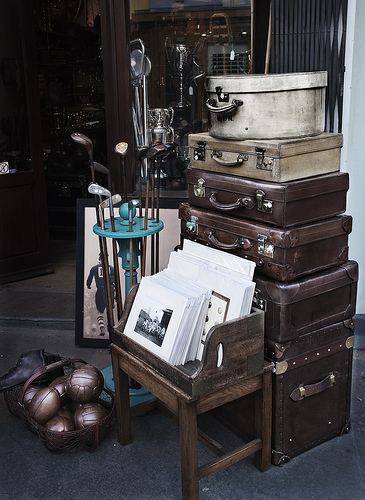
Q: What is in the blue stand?
A: Golf clubs.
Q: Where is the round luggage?
A: On top.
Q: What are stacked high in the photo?
A: Antique suitcases.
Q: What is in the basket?
A: Bronze sport balls.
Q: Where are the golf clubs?
A: In a turquoise stand.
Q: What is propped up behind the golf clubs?
A: A sports picture.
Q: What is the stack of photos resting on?
A: An antique bench.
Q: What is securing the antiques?
A: A front lock gate.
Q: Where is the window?
A: Behind the antiques.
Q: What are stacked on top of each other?
A: Suitcases.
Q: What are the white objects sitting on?
A: They are sitting on a brown chair,.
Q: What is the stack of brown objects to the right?
A: The stack of brown objects is luggage.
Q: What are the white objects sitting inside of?
A: They are sitting in a wooden crate.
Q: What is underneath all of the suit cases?
A: A dark brown trunk.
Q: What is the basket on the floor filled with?
A: It is filled with bronze balls.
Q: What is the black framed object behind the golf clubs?
A: It is a picture of a man.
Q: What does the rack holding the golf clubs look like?
A: It is tall and tortoise blue.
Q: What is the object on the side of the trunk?
A: It is a leather handle.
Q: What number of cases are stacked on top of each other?
A: There are six cases stacked on top of each other.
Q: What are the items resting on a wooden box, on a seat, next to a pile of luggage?
A: Framed photos.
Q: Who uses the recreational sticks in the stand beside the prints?
A: Golfers.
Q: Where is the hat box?
A: At the top of the pile of luggage..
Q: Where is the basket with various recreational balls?
A: At the foot of the seat with the prints on it.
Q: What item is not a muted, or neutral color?
A: The gold club holder.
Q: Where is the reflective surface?
A: Beyond the golf clubs and trophy.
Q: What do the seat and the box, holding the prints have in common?
A: They are both wooden.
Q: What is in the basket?
A: Golden balls.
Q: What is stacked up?
A: Suitcases.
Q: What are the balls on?
A: Basket.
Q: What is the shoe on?
A: Basket.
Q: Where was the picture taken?
A: A store.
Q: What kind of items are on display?
A: Sporting.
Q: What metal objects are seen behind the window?
A: Trophies.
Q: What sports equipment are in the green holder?
A: Golf clubs.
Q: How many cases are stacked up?
A: Six.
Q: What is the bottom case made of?
A: Leather.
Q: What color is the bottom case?
A: Brown.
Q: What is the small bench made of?
A: Wood.